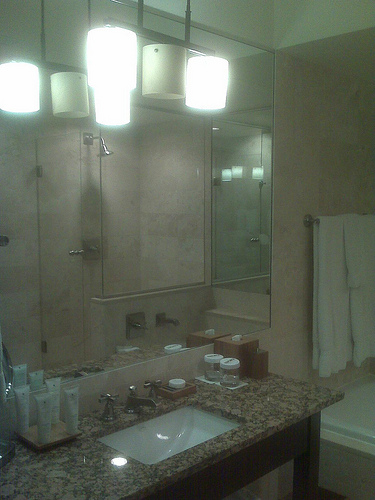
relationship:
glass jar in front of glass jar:
[219, 353, 241, 387] [202, 351, 219, 381]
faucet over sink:
[100, 377, 164, 422] [94, 401, 242, 464]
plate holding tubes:
[17, 419, 80, 447] [14, 377, 80, 441]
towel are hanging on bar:
[311, 210, 351, 370] [302, 210, 318, 227]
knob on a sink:
[98, 390, 117, 423] [98, 403, 239, 466]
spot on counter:
[110, 455, 127, 466] [2, 373, 343, 497]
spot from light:
[110, 455, 127, 466] [82, 24, 136, 126]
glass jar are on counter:
[219, 353, 241, 387] [2, 373, 343, 497]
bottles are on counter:
[11, 375, 80, 443] [2, 373, 343, 497]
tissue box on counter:
[213, 332, 269, 378] [2, 373, 343, 497]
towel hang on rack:
[311, 210, 351, 370] [303, 210, 337, 230]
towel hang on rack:
[337, 213, 373, 360] [303, 210, 337, 230]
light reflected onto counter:
[107, 452, 129, 471] [58, 445, 153, 492]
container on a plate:
[34, 394, 52, 443] [17, 419, 80, 447]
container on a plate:
[58, 384, 83, 430] [17, 419, 80, 447]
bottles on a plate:
[10, 370, 31, 443] [17, 419, 80, 447]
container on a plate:
[47, 373, 64, 424] [17, 419, 80, 447]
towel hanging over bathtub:
[311, 210, 351, 370] [317, 379, 372, 466]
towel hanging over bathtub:
[337, 213, 373, 360] [317, 379, 372, 466]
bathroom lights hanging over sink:
[81, 27, 152, 126] [95, 390, 247, 475]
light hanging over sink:
[178, 40, 243, 122] [95, 390, 247, 475]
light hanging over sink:
[139, 39, 194, 106] [95, 390, 247, 475]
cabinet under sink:
[221, 452, 319, 499] [97, 394, 279, 496]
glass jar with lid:
[202, 351, 219, 381] [202, 349, 222, 366]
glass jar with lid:
[219, 353, 241, 387] [219, 355, 240, 365]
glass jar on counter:
[202, 351, 219, 381] [194, 373, 273, 430]